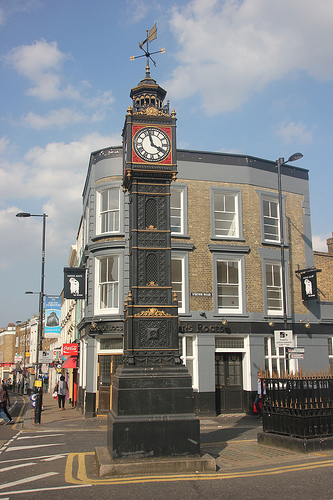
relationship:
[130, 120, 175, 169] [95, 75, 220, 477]
clock attached to a tower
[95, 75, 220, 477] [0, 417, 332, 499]
tower situated between streets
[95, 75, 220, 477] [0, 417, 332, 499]
tower between streets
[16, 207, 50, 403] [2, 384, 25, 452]
light on street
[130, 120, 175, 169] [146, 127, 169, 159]
clock says 3:58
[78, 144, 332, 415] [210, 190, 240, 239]
building has a window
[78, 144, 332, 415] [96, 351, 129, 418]
building has a door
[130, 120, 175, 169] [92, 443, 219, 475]
clock standing on a pedestal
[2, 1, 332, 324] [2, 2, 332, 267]
sky contains clouds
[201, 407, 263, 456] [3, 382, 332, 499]
shadow on ground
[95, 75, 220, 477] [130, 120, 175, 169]
tower contains a clock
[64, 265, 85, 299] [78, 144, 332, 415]
flag on building